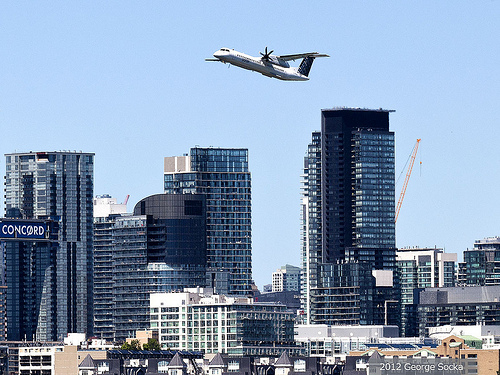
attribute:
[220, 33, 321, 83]
plane — white, large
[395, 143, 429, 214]
crane — yellow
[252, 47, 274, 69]
propeller — black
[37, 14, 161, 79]
sky — clear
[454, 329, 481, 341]
roof — green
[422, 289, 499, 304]
roof — grey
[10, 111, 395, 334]
buildings — tall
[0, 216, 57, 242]
billboard — blue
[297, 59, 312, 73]
tail — blue